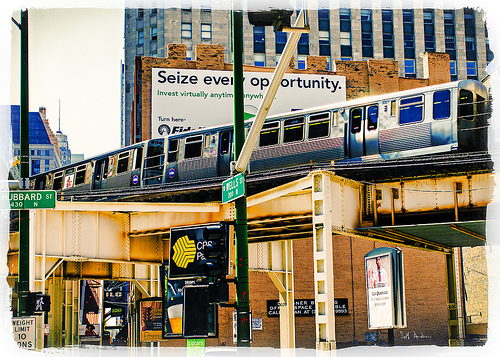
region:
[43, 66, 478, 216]
elevated train passing through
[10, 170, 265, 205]
green and white signs naming street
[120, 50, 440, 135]
large advertisement on side of building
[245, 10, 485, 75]
office tower behind elevated tracks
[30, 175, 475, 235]
angled panels supporting train tracks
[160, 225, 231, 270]
angled yellow lines forming a logo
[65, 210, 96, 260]
rows of bolts in metal supports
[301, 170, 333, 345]
beam with cross bars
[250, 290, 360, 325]
black and white rectangular sign against brick wall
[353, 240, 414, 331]
free-standing sign with advertisement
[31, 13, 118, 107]
Daylight in the town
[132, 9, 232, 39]
Windows in old buyilding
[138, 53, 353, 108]
White, green and blue billboard sign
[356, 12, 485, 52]
Windows in old building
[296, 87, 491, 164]
Shiny silver train moving on tracks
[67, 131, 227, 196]
Shiny silver and blue train moving on tracks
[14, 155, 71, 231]
Green and white street sign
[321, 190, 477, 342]
Sign advertising under train tracks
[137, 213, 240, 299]
Yellow and black sign under train tracks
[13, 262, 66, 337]
White walk signal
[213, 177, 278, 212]
Green and white street sign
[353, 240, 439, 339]
Sign by a street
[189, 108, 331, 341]
Green pole by a street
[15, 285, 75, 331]
Walk sign by a street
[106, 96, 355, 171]
Train above a street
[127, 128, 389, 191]
Silver and blue train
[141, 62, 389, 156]
Green, white and black sign on a building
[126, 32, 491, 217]
Brown brick building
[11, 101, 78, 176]
Blue roof on a building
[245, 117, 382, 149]
Windows on a train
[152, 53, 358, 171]
Tram going through the city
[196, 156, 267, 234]
Street sign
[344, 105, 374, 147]
Tram car doors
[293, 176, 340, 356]
Steel I beam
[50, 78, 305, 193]
Buildings.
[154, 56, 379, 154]
Large advertising sign on the side of a building.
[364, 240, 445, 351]
A advertising sign on the street side.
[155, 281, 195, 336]
Beer advertisement.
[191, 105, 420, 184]
Train going through the city.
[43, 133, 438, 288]
Above ground subway cars.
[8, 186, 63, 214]
Green sign on pole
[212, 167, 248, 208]
Green sign on pole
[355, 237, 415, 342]
Advertisement board on a street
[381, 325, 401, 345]
Pole supporting advertisement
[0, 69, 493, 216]
Train passing though a bridge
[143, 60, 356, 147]
Billboard is white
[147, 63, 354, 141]
Billboard has blue letters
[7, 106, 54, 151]
Roof of building is blue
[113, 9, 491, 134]
Building is tall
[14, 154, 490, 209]
Bridge with train rails